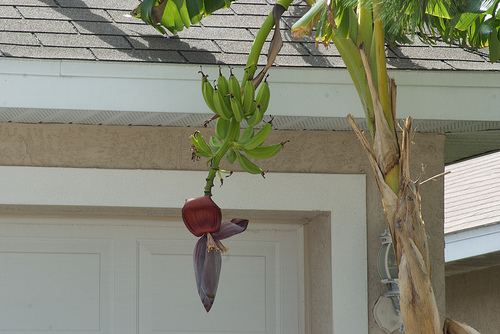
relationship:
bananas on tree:
[184, 64, 292, 187] [133, 0, 499, 334]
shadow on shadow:
[44, 3, 436, 71] [0, 0, 500, 71]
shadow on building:
[0, 0, 500, 71] [0, 2, 499, 333]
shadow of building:
[0, 0, 500, 71] [0, 2, 499, 333]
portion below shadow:
[0, 71, 499, 123] [0, 0, 500, 71]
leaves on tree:
[128, 0, 499, 69] [133, 0, 499, 334]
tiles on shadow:
[1, 0, 417, 58] [0, 0, 500, 71]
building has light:
[0, 0, 499, 334] [375, 216, 438, 324]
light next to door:
[375, 216, 438, 324] [0, 196, 341, 333]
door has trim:
[0, 196, 341, 333] [1, 170, 370, 333]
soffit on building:
[10, 105, 500, 171] [0, 0, 499, 334]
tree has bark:
[133, 0, 499, 334] [348, 36, 444, 333]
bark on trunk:
[348, 36, 444, 333] [309, 8, 454, 333]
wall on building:
[0, 121, 443, 169] [0, 0, 499, 334]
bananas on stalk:
[184, 64, 292, 187] [236, 1, 305, 98]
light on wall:
[375, 216, 438, 324] [1, 120, 450, 334]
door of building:
[0, 196, 341, 333] [0, 0, 499, 334]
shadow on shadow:
[0, 0, 500, 71] [0, 0, 500, 71]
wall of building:
[1, 120, 450, 334] [0, 0, 499, 334]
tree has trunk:
[133, 0, 499, 334] [309, 8, 454, 333]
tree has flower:
[133, 0, 499, 334] [179, 194, 251, 317]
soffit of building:
[10, 105, 500, 171] [0, 0, 499, 334]